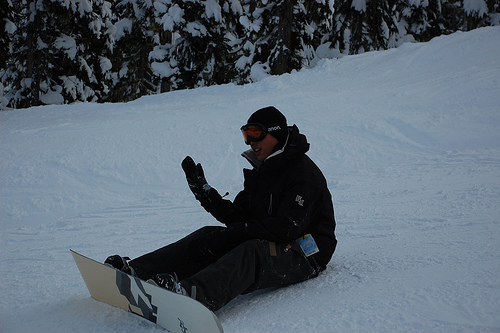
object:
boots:
[145, 273, 186, 295]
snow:
[1, 304, 51, 331]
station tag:
[288, 221, 322, 259]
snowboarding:
[68, 106, 338, 333]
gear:
[110, 107, 340, 309]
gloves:
[181, 155, 209, 195]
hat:
[242, 106, 287, 141]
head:
[241, 106, 288, 153]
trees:
[435, 0, 453, 32]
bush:
[74, 0, 94, 86]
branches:
[0, 0, 29, 108]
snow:
[454, 27, 499, 74]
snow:
[240, 307, 307, 327]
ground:
[3, 262, 287, 328]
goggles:
[240, 124, 283, 144]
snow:
[349, 78, 396, 113]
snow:
[1, 1, 21, 86]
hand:
[180, 156, 208, 193]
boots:
[103, 254, 133, 276]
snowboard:
[66, 249, 222, 333]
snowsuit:
[129, 225, 336, 313]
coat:
[193, 123, 337, 272]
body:
[105, 104, 337, 311]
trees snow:
[241, 56, 270, 78]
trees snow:
[229, 1, 265, 17]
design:
[115, 271, 157, 321]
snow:
[0, 152, 36, 209]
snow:
[189, 88, 275, 102]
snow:
[53, 103, 91, 129]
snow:
[161, 210, 190, 242]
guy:
[103, 106, 338, 313]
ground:
[422, 92, 493, 331]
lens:
[244, 127, 265, 137]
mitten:
[180, 156, 208, 198]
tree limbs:
[487, 0, 500, 25]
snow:
[193, 0, 261, 28]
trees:
[301, 0, 383, 31]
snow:
[86, 0, 138, 33]